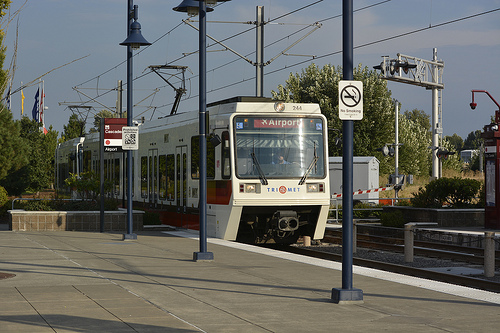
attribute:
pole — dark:
[333, 2, 363, 307]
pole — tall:
[413, 38, 453, 193]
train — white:
[148, 118, 343, 245]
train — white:
[197, 95, 345, 235]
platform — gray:
[51, 233, 299, 330]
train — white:
[58, 86, 360, 222]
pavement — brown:
[2, 228, 498, 330]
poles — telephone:
[195, 51, 209, 264]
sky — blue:
[4, 5, 497, 96]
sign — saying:
[328, 73, 363, 120]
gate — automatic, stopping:
[327, 178, 398, 202]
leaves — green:
[9, 131, 86, 198]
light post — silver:
[395, 49, 456, 186]